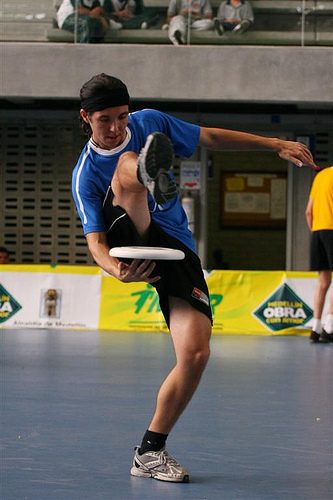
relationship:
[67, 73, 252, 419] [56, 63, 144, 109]
man wearing headband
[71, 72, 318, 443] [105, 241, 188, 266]
man playing with frisbee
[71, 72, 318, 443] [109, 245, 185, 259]
man on frisbee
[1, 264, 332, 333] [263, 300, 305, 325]
fencing with name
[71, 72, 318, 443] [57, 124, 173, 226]
man wearing shirt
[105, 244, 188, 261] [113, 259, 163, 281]
frisbee on fingertips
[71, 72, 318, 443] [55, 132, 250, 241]
man with shirt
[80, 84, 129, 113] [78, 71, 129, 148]
headband on head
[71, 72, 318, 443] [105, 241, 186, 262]
man playing with frisbee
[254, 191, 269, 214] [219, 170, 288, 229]
paper on field bulletin board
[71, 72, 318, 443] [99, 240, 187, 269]
man holding frisbee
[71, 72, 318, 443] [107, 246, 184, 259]
man holding frisbee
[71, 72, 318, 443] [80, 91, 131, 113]
man wearing headband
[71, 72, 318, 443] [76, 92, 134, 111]
man wearing headband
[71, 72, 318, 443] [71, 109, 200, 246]
man wearing shirt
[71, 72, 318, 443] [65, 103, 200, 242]
man wearing shirt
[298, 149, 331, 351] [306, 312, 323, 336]
man wearing sock